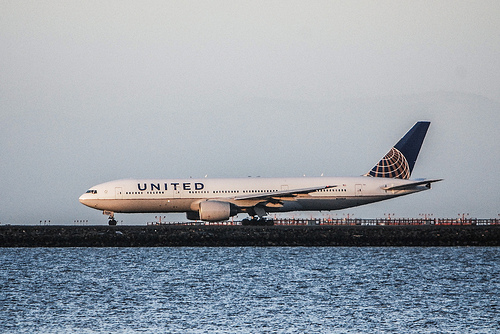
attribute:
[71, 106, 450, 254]
plane — passenger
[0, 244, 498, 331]
water — blue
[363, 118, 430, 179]
tail — blue, yellow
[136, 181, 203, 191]
writing — "united"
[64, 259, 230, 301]
water — calm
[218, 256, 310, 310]
wave — small